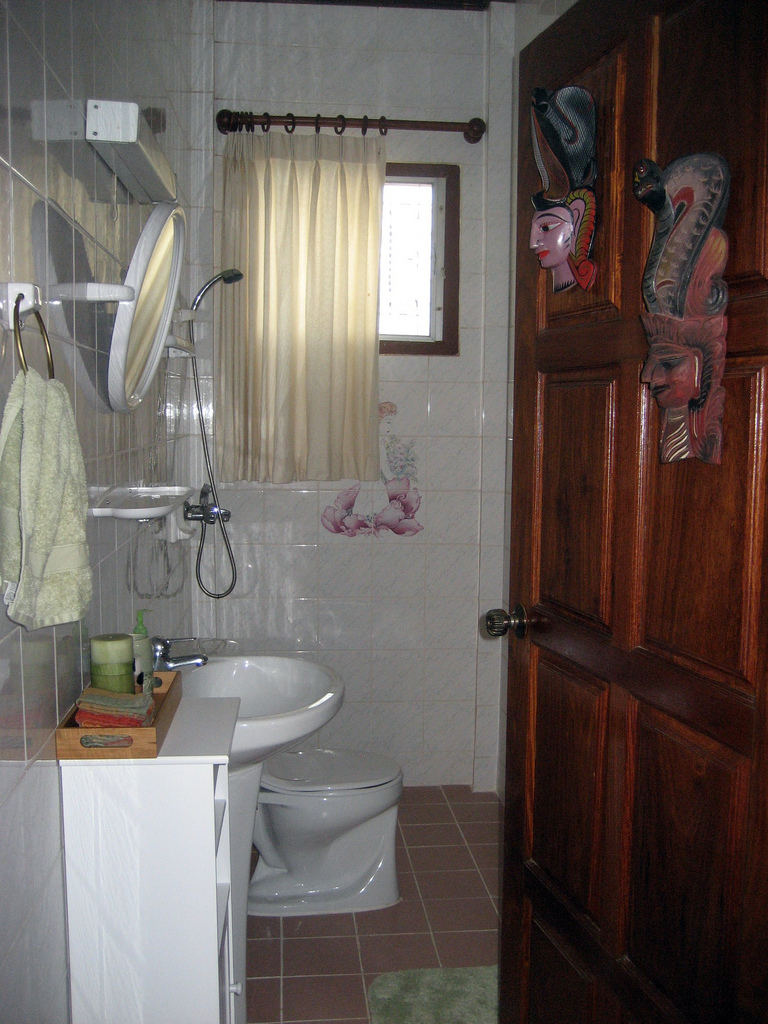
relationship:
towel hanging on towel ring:
[1, 368, 88, 630] [13, 292, 56, 378]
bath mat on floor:
[364, 961, 499, 1022] [249, 787, 498, 1022]